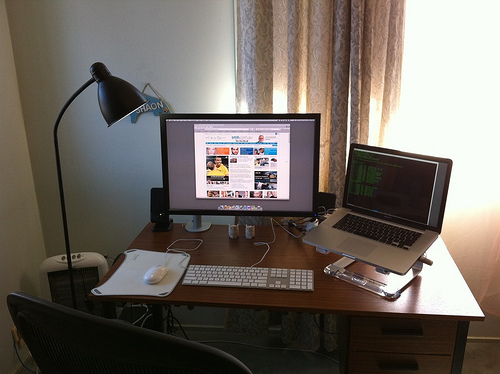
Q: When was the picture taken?
A: Daytime.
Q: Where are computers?
A: On a desk.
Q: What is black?
A: Laptop keys.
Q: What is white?
A: The wall.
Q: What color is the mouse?
A: White.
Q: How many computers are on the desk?
A: Two.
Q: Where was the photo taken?
A: At a desk.